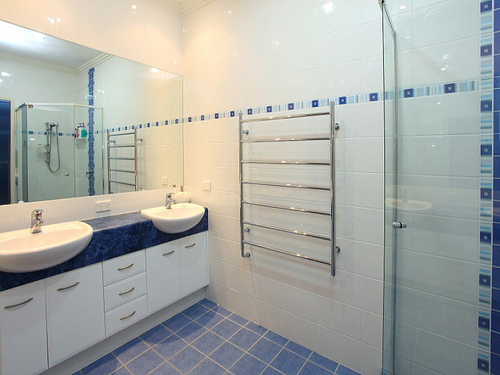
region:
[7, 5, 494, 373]
the bathroom is blue and white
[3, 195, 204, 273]
twin sinks are in the bathroom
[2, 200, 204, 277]
the sinks are oval on the counter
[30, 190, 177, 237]
a dual faucet is chrome on both sinks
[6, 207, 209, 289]
the counter top is blue stone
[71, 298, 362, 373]
the flooring is blue tile in the bathroom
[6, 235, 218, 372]
the bathroom cabinets are white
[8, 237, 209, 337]
chrome hardware is on the cabinets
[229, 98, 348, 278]
a towel warmer is on the wall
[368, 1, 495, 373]
the shower has a clear enclosure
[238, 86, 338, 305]
towel rack on the wall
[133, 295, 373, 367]
tiles on the floor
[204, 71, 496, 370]
tiles on the wall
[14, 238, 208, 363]
handles on the cabinets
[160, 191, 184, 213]
faucet for the sink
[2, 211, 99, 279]
sink in the counter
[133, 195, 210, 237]
bowel of the sink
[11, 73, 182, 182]
reflection in the glass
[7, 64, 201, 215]
mirror on the wall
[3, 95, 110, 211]
shower in the wall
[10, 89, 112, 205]
SHOWER AREA REFLECTED IN MIRROR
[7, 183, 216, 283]
COUNTER HAS DOUBLE SINKS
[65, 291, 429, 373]
FLOOR IS MADE OF BLUE TILES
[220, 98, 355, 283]
TOWEL RACK FOR MULTIPLE TOWELS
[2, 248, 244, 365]
CABINET UNDERNEATH SINK AREA IS WHITE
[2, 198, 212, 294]
COUNTERTOP IS DEEP BLUE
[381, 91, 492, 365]
DOOR APPEARS TO BE TILED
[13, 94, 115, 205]
SHOWER STALL HAS CLEAR WALLS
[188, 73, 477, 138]
TILES ACCENTING WALL ARE DARK BLUE AND LIGHT BLUE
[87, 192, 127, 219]
ELECTRICAL OUTLET BETWEEN SINKS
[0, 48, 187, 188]
it is a mirror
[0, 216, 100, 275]
it is wash passion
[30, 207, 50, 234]
it is water tap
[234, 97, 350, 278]
it is towel holder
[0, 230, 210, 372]
white color cupboard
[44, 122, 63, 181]
water shower pipe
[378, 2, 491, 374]
it is a glass room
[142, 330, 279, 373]
it is blue color tiles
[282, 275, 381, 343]
it is white color tiles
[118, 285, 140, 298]
it is drawer holder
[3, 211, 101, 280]
this is a sink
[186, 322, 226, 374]
this is a tile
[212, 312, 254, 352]
this is a tile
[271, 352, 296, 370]
this is a tile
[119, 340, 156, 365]
this is a tile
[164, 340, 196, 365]
this is a tile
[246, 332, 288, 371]
this is a tile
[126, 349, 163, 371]
this is a tile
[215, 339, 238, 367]
this is a tile